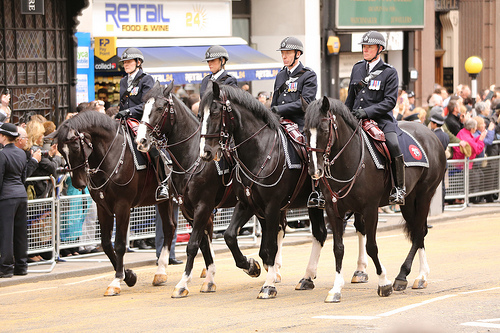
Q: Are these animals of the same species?
A: Yes, all the animals are horses.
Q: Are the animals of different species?
A: No, all the animals are horses.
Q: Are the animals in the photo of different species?
A: No, all the animals are horses.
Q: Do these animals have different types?
A: No, all the animals are horses.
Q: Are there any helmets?
A: Yes, there is a helmet.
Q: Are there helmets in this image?
A: Yes, there is a helmet.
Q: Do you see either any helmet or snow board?
A: Yes, there is a helmet.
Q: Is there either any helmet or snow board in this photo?
A: Yes, there is a helmet.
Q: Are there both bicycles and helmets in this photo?
A: No, there is a helmet but no bikes.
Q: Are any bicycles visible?
A: No, there are no bicycles.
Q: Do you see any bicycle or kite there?
A: No, there are no bicycles or kites.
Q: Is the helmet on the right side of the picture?
A: Yes, the helmet is on the right of the image.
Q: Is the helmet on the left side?
A: No, the helmet is on the right of the image.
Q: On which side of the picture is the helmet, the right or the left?
A: The helmet is on the right of the image.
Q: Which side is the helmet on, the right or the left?
A: The helmet is on the right of the image.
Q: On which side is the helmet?
A: The helmet is on the right of the image.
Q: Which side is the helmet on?
A: The helmet is on the right of the image.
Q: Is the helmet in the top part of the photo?
A: Yes, the helmet is in the top of the image.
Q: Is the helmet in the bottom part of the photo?
A: No, the helmet is in the top of the image.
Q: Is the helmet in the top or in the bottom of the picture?
A: The helmet is in the top of the image.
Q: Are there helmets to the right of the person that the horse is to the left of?
A: Yes, there is a helmet to the right of the person.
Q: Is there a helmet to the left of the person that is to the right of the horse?
A: No, the helmet is to the right of the person.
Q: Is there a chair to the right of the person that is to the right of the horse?
A: No, there is a helmet to the right of the person.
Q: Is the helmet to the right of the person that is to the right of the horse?
A: Yes, the helmet is to the right of the person.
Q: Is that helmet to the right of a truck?
A: No, the helmet is to the right of the person.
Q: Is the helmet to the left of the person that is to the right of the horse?
A: No, the helmet is to the right of the person.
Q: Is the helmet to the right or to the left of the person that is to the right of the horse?
A: The helmet is to the right of the person.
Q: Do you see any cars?
A: No, there are no cars.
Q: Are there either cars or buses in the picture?
A: No, there are no cars or buses.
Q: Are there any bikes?
A: No, there are no bikes.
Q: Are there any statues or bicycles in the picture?
A: No, there are no bicycles or statues.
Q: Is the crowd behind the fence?
A: Yes, the crowd is behind the fence.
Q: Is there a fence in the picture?
A: Yes, there is a fence.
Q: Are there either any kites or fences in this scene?
A: Yes, there is a fence.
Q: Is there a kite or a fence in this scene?
A: Yes, there is a fence.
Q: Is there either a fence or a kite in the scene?
A: Yes, there is a fence.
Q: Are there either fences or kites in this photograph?
A: Yes, there is a fence.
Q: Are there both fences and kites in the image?
A: No, there is a fence but no kites.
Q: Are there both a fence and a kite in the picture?
A: No, there is a fence but no kites.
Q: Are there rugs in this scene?
A: No, there are no rugs.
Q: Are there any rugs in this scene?
A: No, there are no rugs.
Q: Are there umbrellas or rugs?
A: No, there are no rugs or umbrellas.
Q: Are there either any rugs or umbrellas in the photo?
A: No, there are no rugs or umbrellas.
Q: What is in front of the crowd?
A: The fence is in front of the crowd.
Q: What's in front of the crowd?
A: The fence is in front of the crowd.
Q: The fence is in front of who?
A: The fence is in front of the crowd.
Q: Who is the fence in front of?
A: The fence is in front of the crowd.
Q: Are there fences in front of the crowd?
A: Yes, there is a fence in front of the crowd.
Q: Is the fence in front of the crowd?
A: Yes, the fence is in front of the crowd.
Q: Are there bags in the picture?
A: No, there are no bags.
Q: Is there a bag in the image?
A: No, there are no bags.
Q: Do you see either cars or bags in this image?
A: No, there are no bags or cars.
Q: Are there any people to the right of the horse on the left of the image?
A: Yes, there is a person to the right of the horse.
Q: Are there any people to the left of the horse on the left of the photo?
A: No, the person is to the right of the horse.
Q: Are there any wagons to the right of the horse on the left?
A: No, there is a person to the right of the horse.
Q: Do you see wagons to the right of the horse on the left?
A: No, there is a person to the right of the horse.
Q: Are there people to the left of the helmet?
A: Yes, there is a person to the left of the helmet.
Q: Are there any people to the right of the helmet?
A: No, the person is to the left of the helmet.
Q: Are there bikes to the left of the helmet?
A: No, there is a person to the left of the helmet.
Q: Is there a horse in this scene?
A: Yes, there is a horse.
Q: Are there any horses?
A: Yes, there is a horse.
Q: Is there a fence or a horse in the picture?
A: Yes, there is a horse.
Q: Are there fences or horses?
A: Yes, there is a horse.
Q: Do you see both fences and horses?
A: Yes, there are both a horse and a fence.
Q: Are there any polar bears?
A: No, there are no polar bears.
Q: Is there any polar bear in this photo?
A: No, there are no polar bears.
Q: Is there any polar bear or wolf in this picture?
A: No, there are no polar bears or wolves.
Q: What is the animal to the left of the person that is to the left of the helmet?
A: The animal is a horse.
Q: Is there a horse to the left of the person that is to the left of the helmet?
A: Yes, there is a horse to the left of the person.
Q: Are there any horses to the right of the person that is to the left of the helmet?
A: No, the horse is to the left of the person.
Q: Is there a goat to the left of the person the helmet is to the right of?
A: No, there is a horse to the left of the person.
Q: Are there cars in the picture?
A: No, there are no cars.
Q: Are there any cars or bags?
A: No, there are no cars or bags.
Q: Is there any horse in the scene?
A: Yes, there is a horse.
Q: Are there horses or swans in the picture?
A: Yes, there is a horse.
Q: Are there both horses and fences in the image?
A: Yes, there are both a horse and a fence.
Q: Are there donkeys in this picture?
A: No, there are no donkeys.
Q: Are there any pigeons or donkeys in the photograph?
A: No, there are no donkeys or pigeons.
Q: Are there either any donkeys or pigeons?
A: No, there are no donkeys or pigeons.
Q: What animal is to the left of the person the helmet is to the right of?
A: The animal is a horse.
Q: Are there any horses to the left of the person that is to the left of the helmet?
A: Yes, there is a horse to the left of the person.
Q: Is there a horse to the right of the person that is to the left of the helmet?
A: No, the horse is to the left of the person.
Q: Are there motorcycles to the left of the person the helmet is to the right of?
A: No, there is a horse to the left of the person.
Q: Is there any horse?
A: Yes, there is a horse.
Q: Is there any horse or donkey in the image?
A: Yes, there is a horse.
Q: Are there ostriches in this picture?
A: No, there are no ostriches.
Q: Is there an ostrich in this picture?
A: No, there are no ostriches.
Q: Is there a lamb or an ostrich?
A: No, there are no ostriches or lambs.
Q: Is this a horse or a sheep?
A: This is a horse.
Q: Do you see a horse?
A: Yes, there is a horse.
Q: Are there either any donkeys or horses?
A: Yes, there is a horse.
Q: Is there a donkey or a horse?
A: Yes, there is a horse.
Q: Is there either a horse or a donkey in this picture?
A: Yes, there is a horse.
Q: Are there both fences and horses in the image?
A: Yes, there are both a horse and a fence.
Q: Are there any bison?
A: No, there are no bison.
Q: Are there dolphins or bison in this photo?
A: No, there are no bison or dolphins.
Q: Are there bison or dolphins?
A: No, there are no bison or dolphins.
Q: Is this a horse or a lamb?
A: This is a horse.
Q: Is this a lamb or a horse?
A: This is a horse.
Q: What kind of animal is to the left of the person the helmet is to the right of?
A: The animal is a horse.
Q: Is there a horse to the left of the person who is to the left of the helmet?
A: Yes, there is a horse to the left of the person.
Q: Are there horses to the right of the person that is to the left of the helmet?
A: No, the horse is to the left of the person.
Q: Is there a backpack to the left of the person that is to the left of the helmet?
A: No, there is a horse to the left of the person.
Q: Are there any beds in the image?
A: No, there are no beds.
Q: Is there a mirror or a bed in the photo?
A: No, there are no beds or mirrors.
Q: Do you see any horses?
A: Yes, there is a horse.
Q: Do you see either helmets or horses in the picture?
A: Yes, there is a horse.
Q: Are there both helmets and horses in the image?
A: Yes, there are both a horse and a helmet.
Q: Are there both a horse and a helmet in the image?
A: Yes, there are both a horse and a helmet.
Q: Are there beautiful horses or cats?
A: Yes, there is a beautiful horse.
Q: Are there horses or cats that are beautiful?
A: Yes, the horse is beautiful.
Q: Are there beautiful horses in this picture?
A: Yes, there is a beautiful horse.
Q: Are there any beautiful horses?
A: Yes, there is a beautiful horse.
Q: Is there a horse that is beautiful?
A: Yes, there is a horse that is beautiful.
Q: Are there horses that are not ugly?
A: Yes, there is an beautiful horse.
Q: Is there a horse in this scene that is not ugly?
A: Yes, there is an beautiful horse.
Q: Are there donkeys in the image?
A: No, there are no donkeys.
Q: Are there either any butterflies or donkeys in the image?
A: No, there are no donkeys or butterflies.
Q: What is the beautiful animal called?
A: The animal is a horse.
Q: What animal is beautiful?
A: The animal is a horse.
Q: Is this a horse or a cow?
A: This is a horse.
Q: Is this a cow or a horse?
A: This is a horse.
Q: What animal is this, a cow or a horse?
A: This is a horse.